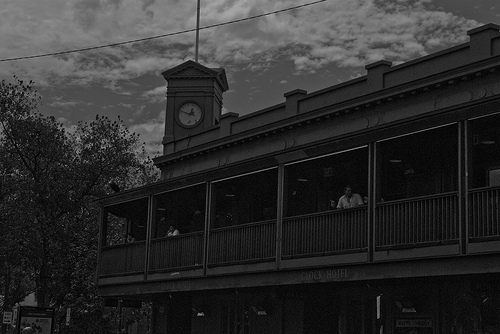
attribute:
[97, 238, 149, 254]
rail — part, long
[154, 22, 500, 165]
roof — part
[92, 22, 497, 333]
castle — part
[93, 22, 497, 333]
house — tip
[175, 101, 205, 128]
clock — part, hotel, 1:50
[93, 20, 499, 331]
building — part, wooden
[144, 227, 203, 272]
fence — wooden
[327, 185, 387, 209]
people — standing, looking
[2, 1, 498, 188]
sky — cloudy, blue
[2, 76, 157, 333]
trees — distant, large, tall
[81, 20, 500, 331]
hotel — brown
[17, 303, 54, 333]
sign — street, named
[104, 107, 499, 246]
windows — multiple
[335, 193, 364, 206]
shirt — white